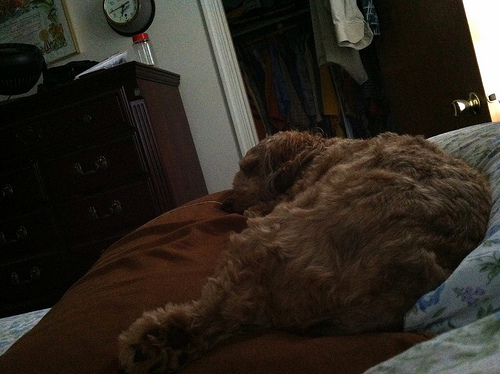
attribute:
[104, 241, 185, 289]
sheets — red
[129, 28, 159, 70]
container — plastic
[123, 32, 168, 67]
bottle — plastic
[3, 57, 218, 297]
dresser — tall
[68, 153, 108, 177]
handle — gold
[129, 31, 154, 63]
container — clear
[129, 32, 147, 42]
lid — red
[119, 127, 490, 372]
dog — brown, furry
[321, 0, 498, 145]
door — open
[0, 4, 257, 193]
wall — white, painted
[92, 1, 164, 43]
clock — partially obscured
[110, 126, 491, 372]
brown dog — furry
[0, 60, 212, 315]
dresser — wood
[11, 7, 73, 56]
certificate — framed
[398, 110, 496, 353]
pillow — white, floral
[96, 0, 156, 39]
clock — round, grey, white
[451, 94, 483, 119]
handle — metal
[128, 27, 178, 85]
bottle — red, clear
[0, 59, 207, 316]
cabinet — dark, wooden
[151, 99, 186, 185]
wood — dark cherry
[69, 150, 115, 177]
handle — metal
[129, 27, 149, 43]
top — red